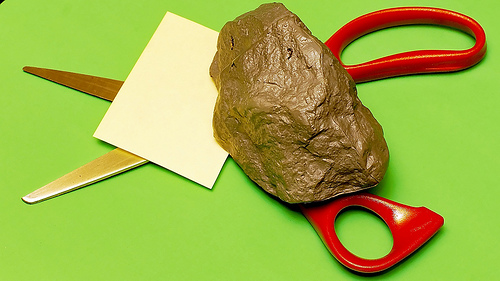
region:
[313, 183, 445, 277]
the red handle of the scissors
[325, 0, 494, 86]
the round handle of the red scissor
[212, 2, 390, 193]
a rock on the scissors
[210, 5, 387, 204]
the brown rock on the green table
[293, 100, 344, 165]
the lines and divets in the rock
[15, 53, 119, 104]
the steel blade of the pair of scissors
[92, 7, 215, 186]
the white square paper on the table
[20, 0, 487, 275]
rock, paper, and scissors on the table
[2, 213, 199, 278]
the green top of the table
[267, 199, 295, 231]
the shadow of the rock on the table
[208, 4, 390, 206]
A large brown shiny rock.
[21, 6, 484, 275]
A pair of silver scissors with red handle.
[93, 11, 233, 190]
A white card above the scissors and under a rock.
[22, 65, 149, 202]
The silver end of scissors.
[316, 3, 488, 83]
Long red handle of the scissors.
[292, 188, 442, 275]
The smaller red handle of the scissors.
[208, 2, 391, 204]
A brown slimy looking rock.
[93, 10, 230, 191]
A white small piece of paper.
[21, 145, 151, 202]
The lighter silver scissor blade.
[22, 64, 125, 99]
A darker shade of silver on the blade.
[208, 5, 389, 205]
an odd looking rock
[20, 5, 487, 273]
a pair of scissors with red handles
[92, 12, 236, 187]
a small piece of white paper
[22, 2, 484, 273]
rock paper scissors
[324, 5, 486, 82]
red plastic scissor handle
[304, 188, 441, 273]
red plastic thumb grip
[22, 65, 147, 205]
some metal scissor blades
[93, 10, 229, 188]
a slip of paper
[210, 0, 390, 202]
a small grey rock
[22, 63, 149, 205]
pointy scissor blades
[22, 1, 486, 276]
A rock, a paper and a pair of scissors.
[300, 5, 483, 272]
Red handles on the scissors.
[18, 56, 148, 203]
Silver metal scissor blades.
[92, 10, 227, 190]
A white piece of paper on top the scissors.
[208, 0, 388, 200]
Brown rock on top of the paper and scissors.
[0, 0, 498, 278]
Scissors on top of a green surface.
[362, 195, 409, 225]
Light reflecting off of the handle of the scissors.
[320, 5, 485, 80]
Large hole in the handles for a thumb.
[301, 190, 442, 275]
Smaller hole in the handles for a finger.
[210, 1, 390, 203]
Surface of the rock has lines and grooves.